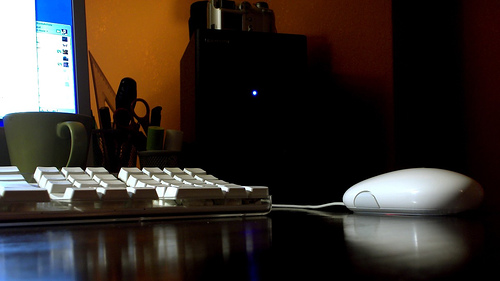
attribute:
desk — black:
[5, 164, 498, 279]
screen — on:
[8, 0, 103, 140]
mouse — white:
[342, 166, 487, 216]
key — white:
[132, 171, 154, 187]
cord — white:
[252, 174, 352, 226]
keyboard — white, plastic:
[0, 151, 275, 226]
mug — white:
[0, 104, 95, 191]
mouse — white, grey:
[314, 164, 496, 216]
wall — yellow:
[77, 2, 387, 182]